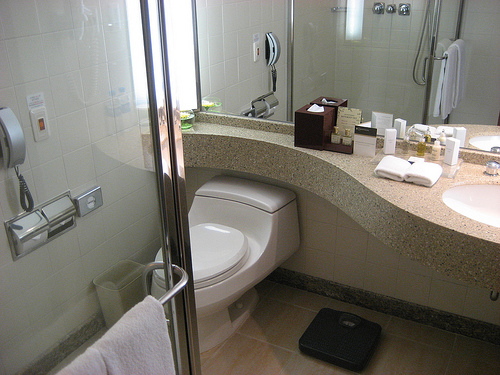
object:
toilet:
[148, 179, 303, 354]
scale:
[297, 306, 382, 371]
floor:
[200, 277, 498, 374]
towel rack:
[157, 265, 190, 306]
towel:
[53, 294, 178, 374]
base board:
[265, 265, 500, 345]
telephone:
[0, 105, 34, 214]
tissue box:
[293, 103, 335, 150]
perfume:
[330, 126, 342, 143]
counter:
[142, 120, 499, 292]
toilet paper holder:
[4, 196, 77, 263]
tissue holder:
[75, 186, 104, 218]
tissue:
[307, 104, 325, 113]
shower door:
[0, 0, 191, 374]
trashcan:
[93, 259, 148, 331]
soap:
[408, 156, 425, 163]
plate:
[369, 147, 463, 180]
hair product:
[431, 141, 441, 161]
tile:
[201, 330, 295, 375]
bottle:
[416, 138, 426, 156]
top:
[420, 138, 425, 142]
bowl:
[179, 109, 195, 133]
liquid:
[181, 114, 196, 130]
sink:
[441, 182, 499, 229]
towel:
[405, 161, 443, 187]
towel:
[374, 155, 412, 183]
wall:
[0, 1, 197, 375]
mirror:
[192, 1, 500, 156]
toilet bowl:
[153, 222, 251, 292]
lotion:
[444, 137, 459, 166]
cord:
[14, 165, 34, 213]